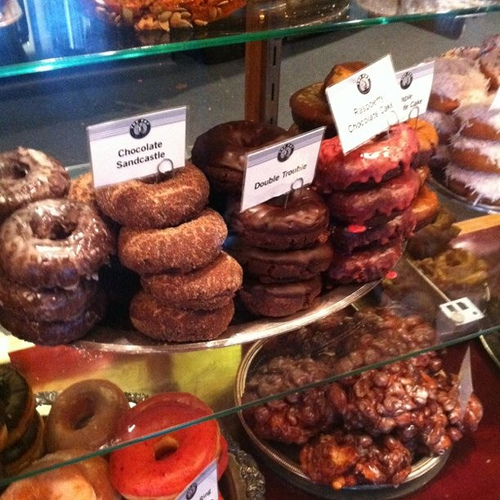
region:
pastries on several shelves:
[22, 14, 488, 496]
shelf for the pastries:
[20, 115, 487, 437]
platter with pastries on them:
[23, 82, 413, 354]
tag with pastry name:
[73, 97, 199, 180]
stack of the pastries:
[240, 117, 325, 310]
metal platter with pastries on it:
[26, 375, 271, 499]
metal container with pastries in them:
[230, 317, 479, 499]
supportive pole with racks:
[238, 15, 300, 127]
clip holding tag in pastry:
[278, 180, 308, 210]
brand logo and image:
[271, 145, 302, 162]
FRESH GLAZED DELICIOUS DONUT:
[2, 192, 113, 295]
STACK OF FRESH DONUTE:
[96, 157, 244, 345]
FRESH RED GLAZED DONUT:
[108, 389, 233, 499]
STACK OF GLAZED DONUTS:
[228, 186, 350, 320]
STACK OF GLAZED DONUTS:
[326, 136, 431, 291]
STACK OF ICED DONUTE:
[447, 97, 498, 209]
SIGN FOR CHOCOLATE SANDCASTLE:
[76, 101, 195, 183]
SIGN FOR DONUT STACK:
[241, 123, 321, 220]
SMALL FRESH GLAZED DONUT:
[43, 368, 130, 447]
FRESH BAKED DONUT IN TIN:
[295, 425, 421, 489]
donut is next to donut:
[1, 144, 69, 218]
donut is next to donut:
[0, 197, 114, 290]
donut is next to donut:
[2, 273, 103, 320]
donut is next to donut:
[0, 288, 103, 345]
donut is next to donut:
[69, 168, 100, 208]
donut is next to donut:
[93, 160, 212, 226]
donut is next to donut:
[119, 207, 226, 275]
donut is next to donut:
[193, 118, 292, 190]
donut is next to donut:
[224, 188, 329, 250]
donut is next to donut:
[229, 232, 332, 284]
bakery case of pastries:
[0, 0, 499, 499]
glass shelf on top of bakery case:
[0, 1, 499, 80]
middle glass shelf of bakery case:
[1, 315, 498, 498]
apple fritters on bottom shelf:
[236, 303, 483, 491]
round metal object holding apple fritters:
[231, 341, 451, 498]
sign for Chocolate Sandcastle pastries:
[84, 99, 196, 190]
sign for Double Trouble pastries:
[240, 124, 330, 215]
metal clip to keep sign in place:
[156, 153, 176, 177]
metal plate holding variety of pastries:
[68, 280, 384, 357]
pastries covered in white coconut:
[421, 36, 499, 208]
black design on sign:
[121, 116, 159, 137]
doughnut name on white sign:
[108, 140, 169, 170]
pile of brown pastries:
[258, 320, 458, 470]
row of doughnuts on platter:
[8, 81, 416, 361]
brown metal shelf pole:
[246, 9, 283, 124]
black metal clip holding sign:
[151, 156, 184, 183]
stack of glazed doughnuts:
[121, 387, 238, 498]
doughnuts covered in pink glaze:
[330, 116, 415, 286]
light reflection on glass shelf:
[33, 7, 99, 52]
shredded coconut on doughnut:
[433, 56, 483, 102]